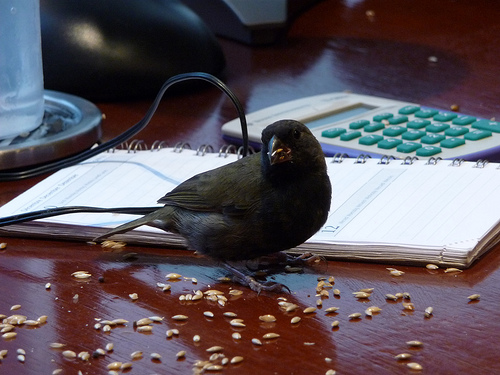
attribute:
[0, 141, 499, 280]
book — computer, close, long, white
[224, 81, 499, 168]
calculator — green, white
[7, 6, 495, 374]
table — wooden, shiny, brown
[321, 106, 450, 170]
buttons — blue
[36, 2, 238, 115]
mouse — black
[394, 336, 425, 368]
pieces — three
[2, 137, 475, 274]
notebook — spiral , ring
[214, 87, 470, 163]
calculator — purple, green, grey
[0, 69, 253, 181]
wire — black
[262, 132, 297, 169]
beak — bird's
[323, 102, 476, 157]
button — green, calculator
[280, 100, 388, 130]
screen — calculator's, off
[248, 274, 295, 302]
foot — bird's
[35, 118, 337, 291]
bird — black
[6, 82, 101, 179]
coaster — small, metal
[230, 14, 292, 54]
base — plastic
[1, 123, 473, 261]
pad — white, note pad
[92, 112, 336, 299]
bird — small, dark, inside, black, close, looking, sitting, tiny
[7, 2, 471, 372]
desk — brown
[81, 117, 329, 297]
bird — dark